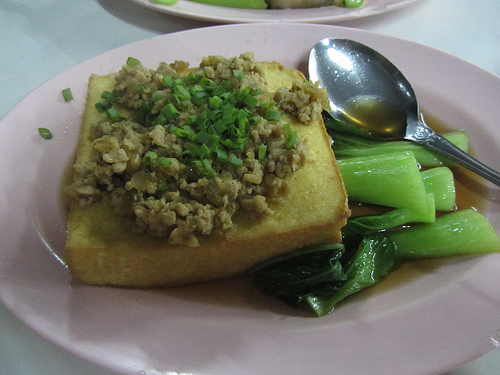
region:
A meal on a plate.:
[8, 28, 484, 351]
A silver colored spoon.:
[298, 39, 498, 199]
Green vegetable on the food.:
[157, 74, 299, 185]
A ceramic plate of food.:
[4, 13, 496, 370]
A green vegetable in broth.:
[251, 127, 498, 336]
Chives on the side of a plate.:
[28, 78, 75, 160]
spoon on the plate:
[311, 35, 498, 189]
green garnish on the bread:
[126, 71, 274, 157]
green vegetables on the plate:
[288, 122, 483, 290]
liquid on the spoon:
[338, 92, 413, 139]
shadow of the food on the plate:
[8, 97, 422, 373]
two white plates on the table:
[2, 2, 499, 372]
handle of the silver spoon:
[430, 129, 499, 181]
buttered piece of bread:
[66, 64, 338, 274]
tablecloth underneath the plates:
[3, 5, 494, 373]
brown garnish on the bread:
[78, 49, 315, 237]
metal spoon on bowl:
[308, 38, 499, 186]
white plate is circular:
[2, 20, 499, 373]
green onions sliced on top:
[36, 55, 298, 189]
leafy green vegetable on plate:
[251, 112, 499, 315]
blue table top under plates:
[1, 0, 498, 373]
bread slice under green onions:
[61, 65, 351, 285]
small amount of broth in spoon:
[336, 95, 406, 142]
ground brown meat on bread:
[66, 55, 325, 243]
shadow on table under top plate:
[94, 0, 433, 32]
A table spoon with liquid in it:
[305, 33, 499, 203]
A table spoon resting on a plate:
[305, 23, 499, 178]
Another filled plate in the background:
[111, 1, 436, 27]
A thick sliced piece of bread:
[66, 59, 354, 294]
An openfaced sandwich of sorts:
[67, 59, 351, 291]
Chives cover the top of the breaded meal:
[66, 58, 351, 288]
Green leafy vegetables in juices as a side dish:
[246, 81, 498, 303]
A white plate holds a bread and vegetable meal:
[5, 22, 495, 371]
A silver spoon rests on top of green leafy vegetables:
[301, 35, 498, 268]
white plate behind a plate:
[106, 0, 429, 25]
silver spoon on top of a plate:
[306, 37, 498, 233]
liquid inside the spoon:
[336, 94, 406, 138]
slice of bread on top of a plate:
[64, 59, 352, 284]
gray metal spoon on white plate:
[303, 33, 499, 186]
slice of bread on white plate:
[65, 58, 342, 288]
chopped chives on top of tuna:
[138, 74, 300, 176]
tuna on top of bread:
[76, 53, 314, 250]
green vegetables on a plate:
[265, 125, 495, 310]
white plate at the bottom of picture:
[1, 20, 499, 371]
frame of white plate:
[137, 0, 422, 19]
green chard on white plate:
[257, 120, 494, 317]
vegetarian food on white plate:
[71, 54, 489, 309]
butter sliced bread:
[66, 59, 344, 281]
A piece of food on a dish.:
[310, 150, 435, 220]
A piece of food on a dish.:
[373, 217, 493, 258]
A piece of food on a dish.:
[326, 132, 483, 169]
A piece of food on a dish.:
[106, 51, 298, 241]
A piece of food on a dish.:
[75, 28, 372, 263]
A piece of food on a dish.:
[71, 32, 376, 301]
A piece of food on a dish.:
[191, 108, 216, 133]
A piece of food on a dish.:
[124, 160, 167, 197]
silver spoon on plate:
[304, 33, 499, 195]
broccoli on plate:
[246, 112, 497, 324]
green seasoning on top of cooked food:
[156, 67, 302, 182]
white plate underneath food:
[1, 20, 497, 374]